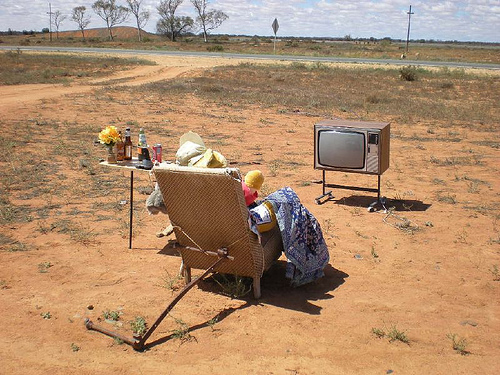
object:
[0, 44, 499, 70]
road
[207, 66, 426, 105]
grass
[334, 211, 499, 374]
ground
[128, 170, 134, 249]
leg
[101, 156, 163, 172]
table